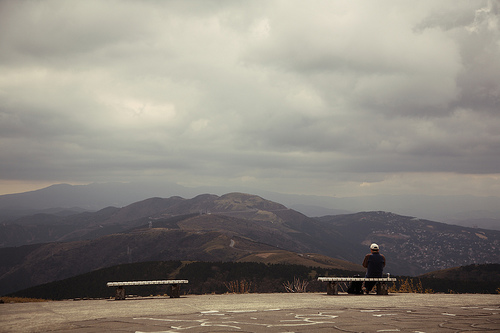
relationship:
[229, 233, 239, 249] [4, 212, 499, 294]
road on hill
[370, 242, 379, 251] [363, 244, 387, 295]
hat on man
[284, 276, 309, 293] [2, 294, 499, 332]
branch on floor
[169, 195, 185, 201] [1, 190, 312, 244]
summit of hill